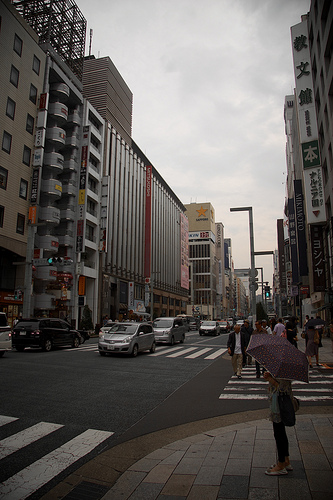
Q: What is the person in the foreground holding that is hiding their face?
A: Umbrella.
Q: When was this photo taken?
A: Daytime.